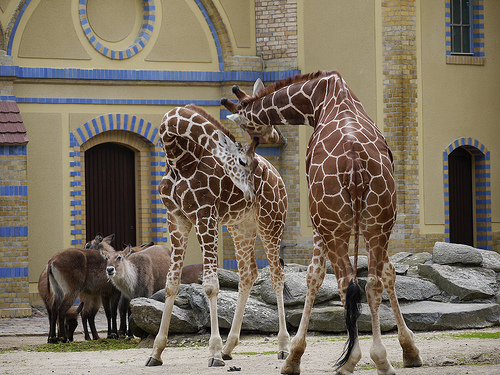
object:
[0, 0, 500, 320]
house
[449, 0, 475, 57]
window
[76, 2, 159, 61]
round architecture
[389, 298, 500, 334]
rocks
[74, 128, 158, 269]
doorway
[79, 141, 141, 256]
door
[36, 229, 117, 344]
deer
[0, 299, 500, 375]
floor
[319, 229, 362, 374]
leg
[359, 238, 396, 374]
leg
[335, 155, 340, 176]
white lines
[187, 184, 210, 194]
white lines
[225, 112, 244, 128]
ears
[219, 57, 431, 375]
giraffe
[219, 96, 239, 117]
horn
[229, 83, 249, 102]
horn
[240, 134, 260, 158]
horn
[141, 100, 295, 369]
giraffe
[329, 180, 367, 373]
tail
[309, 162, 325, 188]
spots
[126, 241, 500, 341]
rock pile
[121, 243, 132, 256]
ears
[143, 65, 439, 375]
two giraffes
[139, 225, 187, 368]
leg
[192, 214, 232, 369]
leg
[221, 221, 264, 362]
leg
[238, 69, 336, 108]
mane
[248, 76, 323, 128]
neck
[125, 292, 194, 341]
rock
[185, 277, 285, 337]
rock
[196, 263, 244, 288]
rock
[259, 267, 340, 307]
rock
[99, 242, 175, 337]
deer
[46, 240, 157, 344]
deer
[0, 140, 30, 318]
wall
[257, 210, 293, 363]
legs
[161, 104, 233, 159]
neck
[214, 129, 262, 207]
head